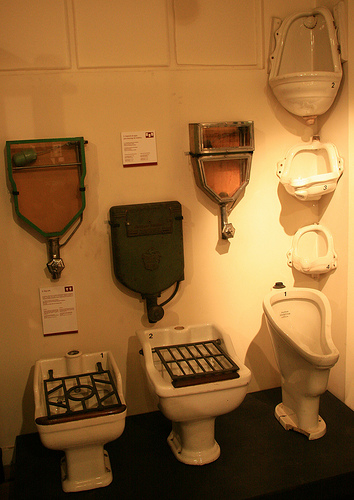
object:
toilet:
[27, 346, 128, 492]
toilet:
[134, 317, 251, 466]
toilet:
[258, 283, 341, 445]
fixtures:
[268, 3, 348, 277]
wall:
[0, 24, 268, 123]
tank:
[106, 195, 188, 327]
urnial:
[258, 7, 349, 126]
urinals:
[271, 131, 350, 285]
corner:
[287, 0, 335, 39]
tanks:
[3, 116, 255, 322]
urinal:
[250, 286, 343, 442]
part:
[41, 355, 121, 423]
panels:
[0, 0, 267, 73]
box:
[258, 445, 338, 491]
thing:
[5, 140, 39, 165]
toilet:
[136, 325, 251, 468]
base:
[58, 449, 129, 499]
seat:
[150, 337, 239, 388]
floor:
[6, 380, 354, 499]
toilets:
[32, 288, 342, 484]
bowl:
[266, 286, 336, 365]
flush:
[221, 206, 235, 240]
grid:
[43, 365, 123, 422]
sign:
[34, 281, 80, 337]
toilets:
[269, 138, 340, 432]